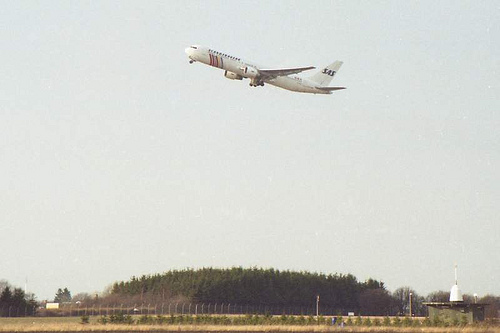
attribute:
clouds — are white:
[0, 0, 498, 300]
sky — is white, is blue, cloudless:
[2, 0, 498, 302]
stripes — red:
[208, 52, 218, 69]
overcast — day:
[0, 1, 497, 301]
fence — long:
[59, 267, 442, 327]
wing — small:
[313, 82, 347, 94]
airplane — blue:
[175, 17, 381, 109]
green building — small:
[425, 302, 488, 328]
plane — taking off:
[186, 42, 348, 113]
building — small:
[41, 299, 64, 312]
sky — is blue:
[376, 43, 494, 247]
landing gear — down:
[247, 79, 267, 89]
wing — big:
[268, 54, 311, 86]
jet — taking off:
[166, 23, 374, 132]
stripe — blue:
[210, 50, 222, 67]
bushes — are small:
[78, 314, 470, 329]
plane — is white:
[187, 40, 348, 95]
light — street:
[300, 277, 328, 318]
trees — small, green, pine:
[77, 309, 474, 331]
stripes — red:
[210, 52, 223, 67]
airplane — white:
[180, 38, 348, 108]